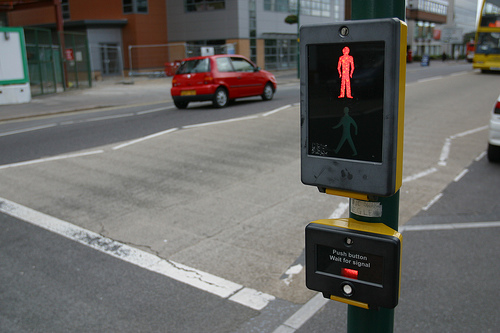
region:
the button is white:
[342, 283, 352, 294]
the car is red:
[172, 52, 277, 108]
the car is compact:
[172, 53, 277, 110]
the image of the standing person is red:
[337, 45, 354, 98]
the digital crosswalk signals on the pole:
[298, 0, 405, 332]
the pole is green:
[348, 0, 406, 331]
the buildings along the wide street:
[0, 0, 499, 331]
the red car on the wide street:
[0, 55, 498, 331]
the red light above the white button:
[342, 265, 358, 295]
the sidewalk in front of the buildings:
[0, 0, 497, 122]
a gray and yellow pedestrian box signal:
[296, 18, 409, 192]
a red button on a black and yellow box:
[304, 219, 399, 309]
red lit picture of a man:
[336, 45, 354, 99]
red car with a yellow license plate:
[170, 53, 276, 109]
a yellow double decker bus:
[470, 2, 498, 70]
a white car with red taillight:
[487, 96, 499, 162]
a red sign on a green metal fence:
[22, 24, 91, 95]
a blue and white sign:
[418, 52, 430, 67]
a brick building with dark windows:
[2, 0, 167, 73]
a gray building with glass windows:
[165, 0, 344, 79]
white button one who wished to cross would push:
[342, 285, 353, 294]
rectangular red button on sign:
[339, 264, 359, 276]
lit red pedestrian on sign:
[332, 45, 359, 100]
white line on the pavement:
[1, 197, 273, 309]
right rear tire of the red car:
[212, 85, 231, 107]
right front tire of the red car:
[262, 82, 277, 102]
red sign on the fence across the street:
[63, 46, 75, 62]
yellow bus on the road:
[473, 1, 499, 71]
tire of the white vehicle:
[487, 144, 499, 166]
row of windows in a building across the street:
[413, 0, 449, 14]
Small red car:
[167, 51, 279, 111]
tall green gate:
[20, 22, 95, 100]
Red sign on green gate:
[56, 28, 94, 93]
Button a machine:
[340, 281, 354, 297]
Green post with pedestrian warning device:
[295, 0, 411, 332]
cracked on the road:
[81, 210, 233, 295]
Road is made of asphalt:
[0, 55, 498, 330]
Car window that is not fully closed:
[226, 54, 253, 74]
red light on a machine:
[338, 266, 359, 279]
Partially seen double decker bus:
[470, 1, 498, 76]